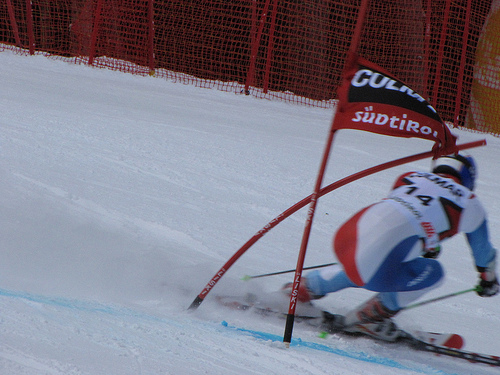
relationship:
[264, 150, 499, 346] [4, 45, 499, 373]
person skiing down slope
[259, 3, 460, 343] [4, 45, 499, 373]
ski flag sticking from slope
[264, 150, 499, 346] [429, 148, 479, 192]
person has head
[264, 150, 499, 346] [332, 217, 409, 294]
person has back side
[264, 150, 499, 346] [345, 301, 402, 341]
person has right shoe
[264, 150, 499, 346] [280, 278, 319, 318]
person has left shoe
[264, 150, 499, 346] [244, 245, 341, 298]
person has left ski pole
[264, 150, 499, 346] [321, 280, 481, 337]
person has right ski pole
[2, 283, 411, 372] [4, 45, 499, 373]
line painted on slope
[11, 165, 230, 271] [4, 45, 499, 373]
track in slope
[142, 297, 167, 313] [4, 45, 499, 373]
hole in slope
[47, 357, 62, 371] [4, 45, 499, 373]
hole in slope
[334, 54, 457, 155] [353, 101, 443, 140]
flag has word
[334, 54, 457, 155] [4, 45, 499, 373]
flag in slope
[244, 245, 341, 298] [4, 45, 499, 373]
left ski pole above slope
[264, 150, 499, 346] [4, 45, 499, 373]
person going down slope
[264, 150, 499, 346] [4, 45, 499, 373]
person skiing on slope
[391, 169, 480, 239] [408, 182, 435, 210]
back has number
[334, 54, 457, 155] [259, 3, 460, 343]
flag on top of ski flag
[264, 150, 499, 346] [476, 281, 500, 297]
person has hand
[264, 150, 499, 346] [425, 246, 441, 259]
person has hand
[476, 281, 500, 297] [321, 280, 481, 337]
hand has right ski pole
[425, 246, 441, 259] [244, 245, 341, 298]
hand has left ski pole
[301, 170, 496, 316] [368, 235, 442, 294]
uniform has design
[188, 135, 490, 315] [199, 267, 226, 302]
pole has letters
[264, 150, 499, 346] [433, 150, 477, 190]
person has helmet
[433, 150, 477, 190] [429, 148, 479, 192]
helmet on top of head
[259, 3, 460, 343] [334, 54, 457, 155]
ski flag has flag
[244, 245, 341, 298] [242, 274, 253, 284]
left ski pole has tip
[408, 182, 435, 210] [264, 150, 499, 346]
number on back of person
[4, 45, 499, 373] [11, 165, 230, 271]
slope has track